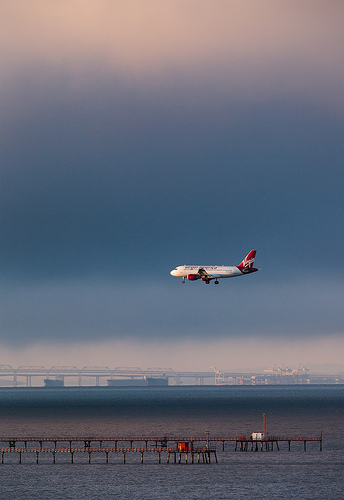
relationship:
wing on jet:
[237, 249, 256, 267] [168, 248, 258, 287]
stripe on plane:
[241, 256, 255, 264] [147, 234, 302, 302]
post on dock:
[207, 447, 222, 463] [0, 445, 218, 464]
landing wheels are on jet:
[198, 274, 220, 285] [168, 248, 258, 287]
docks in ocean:
[0, 430, 325, 450] [0, 383, 343, 499]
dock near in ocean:
[0, 435, 322, 451] [0, 383, 343, 499]